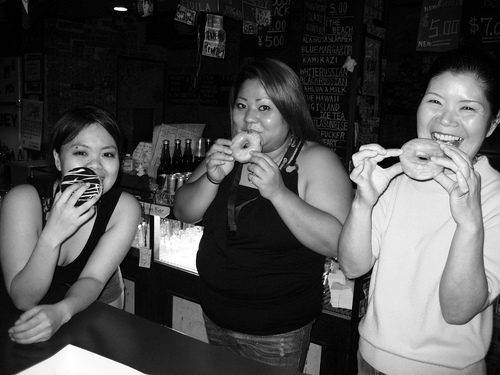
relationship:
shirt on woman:
[357, 155, 500, 375] [337, 43, 497, 373]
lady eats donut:
[198, 90, 366, 347] [201, 140, 256, 170]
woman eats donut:
[171, 52, 351, 372] [224, 126, 264, 167]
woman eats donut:
[337, 43, 497, 373] [397, 135, 447, 183]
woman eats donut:
[0, 109, 143, 345] [50, 161, 108, 208]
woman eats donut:
[171, 52, 351, 372] [224, 126, 269, 167]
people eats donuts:
[5, 52, 496, 366] [57, 126, 449, 207]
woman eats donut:
[5, 103, 143, 346] [57, 163, 104, 204]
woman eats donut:
[337, 43, 497, 373] [395, 132, 453, 182]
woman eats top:
[0, 109, 143, 345] [4, 187, 136, 345]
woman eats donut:
[5, 103, 143, 346] [395, 135, 449, 185]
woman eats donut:
[171, 52, 351, 372] [228, 130, 264, 161]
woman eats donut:
[337, 43, 497, 373] [53, 164, 106, 208]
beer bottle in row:
[154, 134, 177, 195] [150, 130, 215, 204]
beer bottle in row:
[169, 127, 181, 193] [150, 130, 215, 204]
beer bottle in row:
[180, 130, 194, 190] [150, 130, 215, 204]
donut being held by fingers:
[391, 136, 456, 183] [426, 155, 455, 170]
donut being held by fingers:
[391, 136, 456, 183] [438, 145, 468, 166]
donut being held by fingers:
[391, 136, 456, 183] [375, 144, 405, 160]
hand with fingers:
[349, 141, 404, 207] [379, 144, 400, 162]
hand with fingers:
[349, 141, 404, 207] [379, 161, 406, 181]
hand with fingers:
[349, 141, 404, 207] [350, 141, 385, 175]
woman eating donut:
[0, 109, 143, 345] [393, 132, 448, 181]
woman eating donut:
[171, 58, 352, 375] [393, 132, 448, 181]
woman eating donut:
[337, 63, 500, 375] [393, 132, 448, 181]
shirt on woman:
[373, 187, 487, 322] [369, 74, 497, 222]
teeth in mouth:
[433, 134, 460, 143] [428, 128, 460, 150]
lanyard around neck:
[218, 132, 303, 237] [223, 132, 309, 163]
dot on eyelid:
[72, 143, 82, 151] [69, 142, 89, 152]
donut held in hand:
[33, 163, 134, 265] [43, 180, 98, 244]